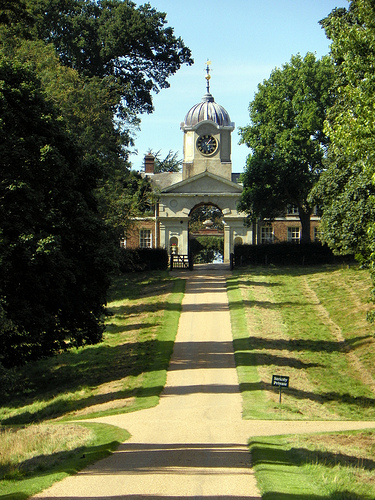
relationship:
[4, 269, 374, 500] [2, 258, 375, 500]
shadows are on ground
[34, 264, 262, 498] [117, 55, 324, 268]
path leads to building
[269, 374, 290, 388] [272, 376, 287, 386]
sign says private property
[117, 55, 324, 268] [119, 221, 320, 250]
building has many windows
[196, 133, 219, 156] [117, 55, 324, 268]
clock on building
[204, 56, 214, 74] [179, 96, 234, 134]
cross on roof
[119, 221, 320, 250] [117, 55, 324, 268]
many windows are on building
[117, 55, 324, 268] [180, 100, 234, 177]
building with clock tower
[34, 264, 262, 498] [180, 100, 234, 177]
path leads to clock tower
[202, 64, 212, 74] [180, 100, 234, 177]
weather vane on top of clock tower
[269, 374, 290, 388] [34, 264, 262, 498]
sign by path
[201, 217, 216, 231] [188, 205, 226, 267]
fountain through entrance